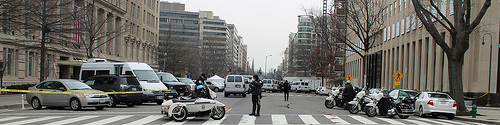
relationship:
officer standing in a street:
[244, 69, 262, 118] [0, 87, 499, 124]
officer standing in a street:
[195, 72, 206, 90] [0, 87, 499, 124]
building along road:
[337, 1, 499, 111] [0, 79, 496, 125]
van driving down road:
[224, 72, 244, 93] [0, 79, 496, 125]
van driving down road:
[258, 75, 276, 92] [0, 79, 496, 125]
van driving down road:
[288, 82, 309, 91] [0, 79, 496, 125]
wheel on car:
[65, 97, 83, 112] [21, 79, 115, 111]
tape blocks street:
[1, 87, 170, 98] [215, 92, 324, 123]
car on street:
[21, 79, 111, 109] [117, 98, 347, 123]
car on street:
[87, 76, 139, 105] [117, 98, 347, 123]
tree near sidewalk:
[7, 2, 81, 82] [1, 91, 25, 106]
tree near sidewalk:
[72, 1, 129, 59] [1, 91, 25, 106]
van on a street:
[222, 74, 247, 98] [241, 98, 289, 121]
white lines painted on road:
[37, 108, 360, 123] [9, 79, 497, 123]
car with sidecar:
[156, 91, 229, 123] [162, 83, 236, 118]